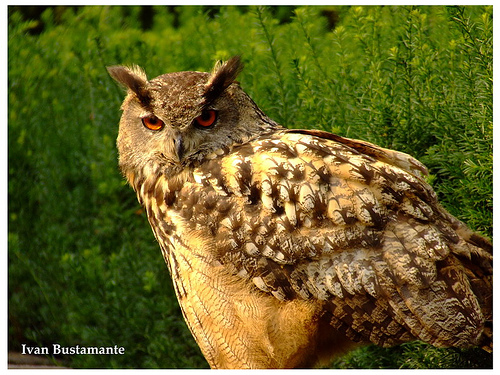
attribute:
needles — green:
[387, 5, 426, 156]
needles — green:
[446, 5, 491, 108]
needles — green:
[249, 3, 292, 117]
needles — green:
[292, 6, 342, 130]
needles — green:
[89, 32, 125, 103]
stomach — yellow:
[170, 232, 301, 363]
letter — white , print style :
[20, 343, 27, 353]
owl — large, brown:
[104, 51, 491, 369]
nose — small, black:
[173, 130, 191, 162]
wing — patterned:
[210, 134, 391, 228]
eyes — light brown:
[141, 106, 217, 131]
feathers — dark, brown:
[168, 118, 494, 356]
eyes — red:
[140, 110, 218, 130]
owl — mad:
[88, 27, 484, 337]